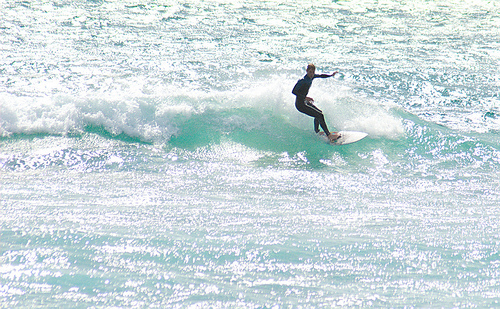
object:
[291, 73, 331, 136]
wet suit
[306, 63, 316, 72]
hair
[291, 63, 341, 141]
man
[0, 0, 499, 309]
water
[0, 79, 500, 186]
waves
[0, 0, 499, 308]
surface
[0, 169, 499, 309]
ripples